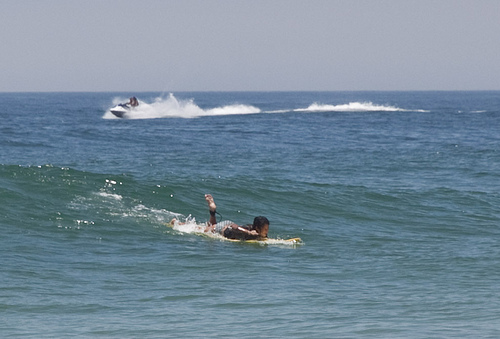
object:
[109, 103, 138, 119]
jet ski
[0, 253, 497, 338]
water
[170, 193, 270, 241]
person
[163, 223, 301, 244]
surfboard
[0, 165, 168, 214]
wave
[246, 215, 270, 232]
hair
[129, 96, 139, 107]
person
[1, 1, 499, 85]
sky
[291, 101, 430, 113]
wave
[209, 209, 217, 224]
leg